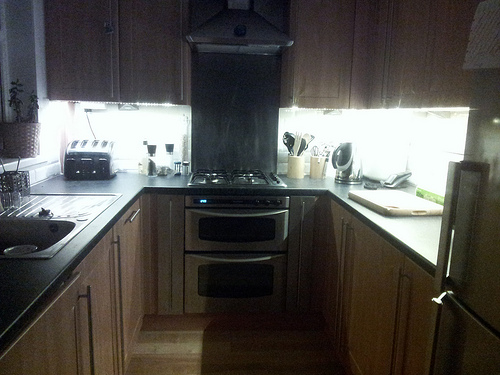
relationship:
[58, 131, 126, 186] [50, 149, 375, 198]
toaster on counter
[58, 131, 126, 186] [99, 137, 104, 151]
toaster has slots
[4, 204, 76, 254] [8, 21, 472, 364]
sink on side of th kitchen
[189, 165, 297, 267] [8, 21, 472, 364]
oven range in middle of kitchen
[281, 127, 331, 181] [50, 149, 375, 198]
utensils are on counter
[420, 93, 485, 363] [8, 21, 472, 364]
refrigerator in kitchen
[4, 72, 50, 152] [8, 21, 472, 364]
plant in kitchen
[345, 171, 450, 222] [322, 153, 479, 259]
cutting board on counter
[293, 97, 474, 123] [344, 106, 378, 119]
light very bright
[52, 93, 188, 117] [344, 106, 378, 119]
light very bright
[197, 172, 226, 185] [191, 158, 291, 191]
burners for stove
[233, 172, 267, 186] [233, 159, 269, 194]
burner on right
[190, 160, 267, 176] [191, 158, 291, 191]
back burner on stove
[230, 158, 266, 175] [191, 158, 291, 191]
right burner on stove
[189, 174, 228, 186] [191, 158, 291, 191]
front left burner on stove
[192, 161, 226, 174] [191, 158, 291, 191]
back left burner on stove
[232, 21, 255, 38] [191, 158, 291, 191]
blue light on stove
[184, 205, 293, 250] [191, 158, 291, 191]
top oven on stove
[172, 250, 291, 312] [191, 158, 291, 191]
bottom oven on stove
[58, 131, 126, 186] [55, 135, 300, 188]
toaster sitting on cabinet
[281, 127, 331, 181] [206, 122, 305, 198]
utensils used for cooking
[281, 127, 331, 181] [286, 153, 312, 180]
utensils in a vase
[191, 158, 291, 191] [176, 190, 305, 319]
range top above oven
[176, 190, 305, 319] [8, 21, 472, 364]
oven in kitchen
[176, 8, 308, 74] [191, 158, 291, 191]
range hood above stove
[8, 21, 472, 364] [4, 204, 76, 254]
kitchen has a sink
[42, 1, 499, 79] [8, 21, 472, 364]
cabinets in kitchen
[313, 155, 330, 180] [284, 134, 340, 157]
holder full of spoons and spatulas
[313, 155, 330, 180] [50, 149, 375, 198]
holder on counter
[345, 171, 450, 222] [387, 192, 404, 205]
cutting board made of wood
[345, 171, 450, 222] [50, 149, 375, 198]
cutting board on counter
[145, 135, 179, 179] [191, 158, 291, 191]
grinders to left of stove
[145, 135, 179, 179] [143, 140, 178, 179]
grinders for salt & pepper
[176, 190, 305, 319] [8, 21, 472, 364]
two ovens in kitchen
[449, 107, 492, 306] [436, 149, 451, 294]
freezer has a handle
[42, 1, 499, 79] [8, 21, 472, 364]
cabinets are in kitchen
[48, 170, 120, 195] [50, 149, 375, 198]
small part of counter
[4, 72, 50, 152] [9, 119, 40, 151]
plant in a basket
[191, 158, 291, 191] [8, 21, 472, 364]
stove in kitchen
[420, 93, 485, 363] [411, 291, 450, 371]
refrigerator has a handle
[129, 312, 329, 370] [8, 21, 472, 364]
floor in kitchen